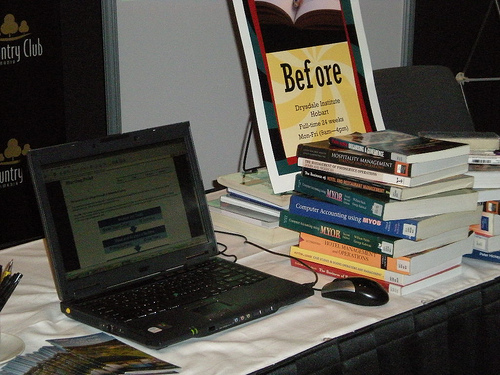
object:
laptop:
[21, 117, 318, 351]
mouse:
[317, 273, 392, 309]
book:
[284, 243, 465, 287]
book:
[277, 208, 473, 259]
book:
[286, 192, 485, 243]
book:
[297, 140, 472, 179]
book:
[325, 125, 474, 166]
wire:
[210, 225, 328, 296]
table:
[0, 127, 500, 375]